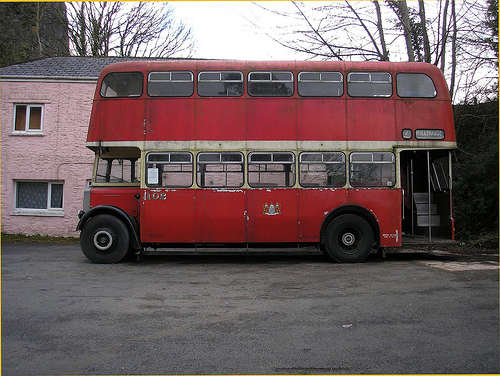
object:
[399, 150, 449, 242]
door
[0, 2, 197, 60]
tree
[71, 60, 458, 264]
bus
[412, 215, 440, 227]
stair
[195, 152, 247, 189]
windows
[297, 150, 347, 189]
windows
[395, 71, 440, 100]
window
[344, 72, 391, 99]
window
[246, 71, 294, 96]
window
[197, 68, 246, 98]
window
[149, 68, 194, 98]
window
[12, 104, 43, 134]
window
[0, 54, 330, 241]
building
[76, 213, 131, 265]
wheel